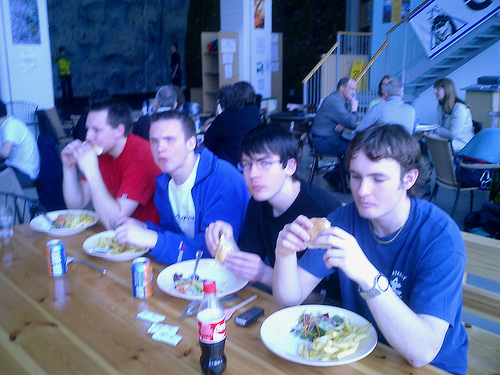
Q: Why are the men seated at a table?
A: They are eating.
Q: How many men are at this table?
A: Four.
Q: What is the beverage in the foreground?
A: Coca-Cola.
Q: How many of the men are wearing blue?
A: Two.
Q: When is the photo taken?
A: Daytime.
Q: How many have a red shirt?
A: One.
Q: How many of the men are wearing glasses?
A: One.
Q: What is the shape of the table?
A: Rectangular.